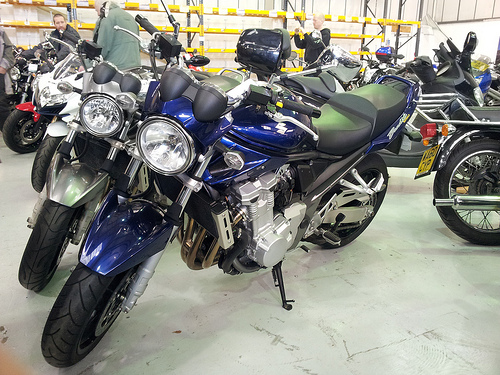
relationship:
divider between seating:
[334, 90, 377, 139] [354, 71, 407, 135]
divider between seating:
[334, 90, 377, 139] [305, 97, 370, 156]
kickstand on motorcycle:
[268, 264, 298, 314] [30, 6, 422, 368]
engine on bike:
[213, 175, 327, 267] [41, 13, 422, 368]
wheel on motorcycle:
[41, 263, 142, 367] [405, 87, 499, 251]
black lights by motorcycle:
[160, 66, 230, 128] [16, 39, 152, 297]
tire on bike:
[9, 191, 87, 293] [41, 13, 422, 368]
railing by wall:
[5, 0, 423, 84] [9, 0, 499, 78]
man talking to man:
[42, 12, 83, 53] [89, 1, 144, 73]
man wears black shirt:
[290, 13, 332, 63] [281, 16, 373, 81]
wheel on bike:
[41, 229, 155, 365] [41, 33, 422, 365]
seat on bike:
[310, 87, 373, 149] [41, 33, 422, 365]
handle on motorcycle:
[283, 100, 320, 117] [30, 6, 422, 368]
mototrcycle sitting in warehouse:
[30, 70, 437, 345] [3, 2, 498, 372]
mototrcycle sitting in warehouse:
[415, 98, 500, 246] [3, 2, 498, 372]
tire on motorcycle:
[39, 258, 129, 367] [30, 6, 422, 368]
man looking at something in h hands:
[294, 13, 333, 58] [292, 27, 311, 38]